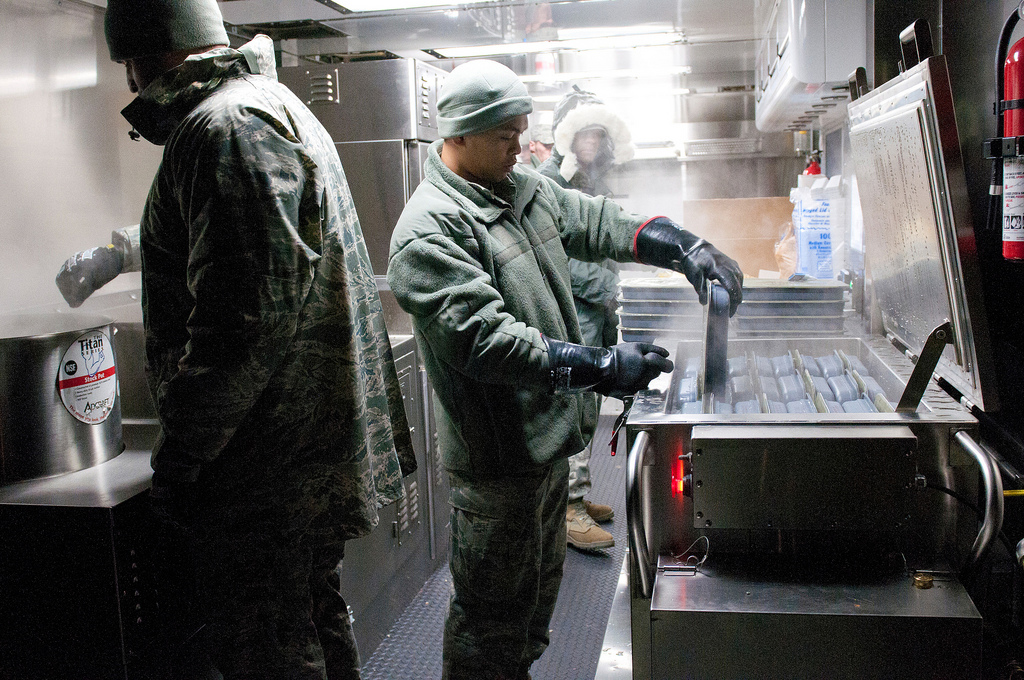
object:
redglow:
[670, 438, 686, 498]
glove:
[540, 332, 674, 392]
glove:
[633, 216, 744, 318]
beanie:
[435, 58, 533, 139]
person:
[55, 0, 420, 680]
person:
[537, 86, 634, 550]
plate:
[703, 280, 731, 403]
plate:
[729, 369, 754, 401]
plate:
[757, 375, 781, 400]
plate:
[777, 369, 807, 405]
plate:
[814, 392, 844, 413]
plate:
[842, 392, 879, 413]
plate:
[827, 374, 858, 404]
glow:
[662, 426, 691, 556]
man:
[384, 58, 742, 680]